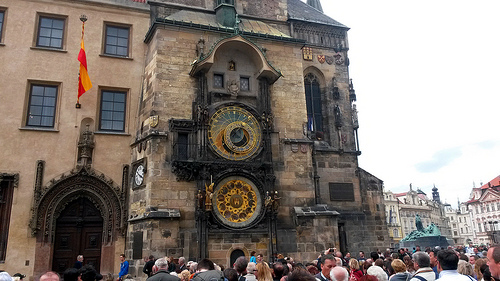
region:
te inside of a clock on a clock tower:
[205, 103, 280, 231]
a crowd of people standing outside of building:
[0, 248, 496, 278]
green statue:
[395, 210, 441, 250]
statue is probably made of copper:
[402, 210, 447, 248]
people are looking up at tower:
[0, 252, 481, 273]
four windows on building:
[25, 11, 126, 137]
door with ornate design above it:
[30, 115, 122, 275]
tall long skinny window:
[300, 60, 337, 141]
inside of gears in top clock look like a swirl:
[210, 97, 267, 164]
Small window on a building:
[28, 6, 68, 60]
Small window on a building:
[88, 11, 134, 73]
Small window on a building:
[212, 70, 222, 91]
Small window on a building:
[237, 72, 252, 98]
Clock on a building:
[123, 154, 158, 189]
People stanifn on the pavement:
[12, 245, 100, 280]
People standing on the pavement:
[145, 247, 258, 280]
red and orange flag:
[62, 36, 107, 112]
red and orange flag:
[56, 32, 101, 107]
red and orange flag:
[53, 20, 103, 123]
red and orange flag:
[65, 31, 106, 133]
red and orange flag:
[67, 30, 102, 115]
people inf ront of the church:
[132, 237, 438, 277]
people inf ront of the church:
[115, 91, 415, 276]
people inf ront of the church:
[142, 158, 450, 278]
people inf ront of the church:
[143, 156, 465, 279]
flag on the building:
[79, 9, 99, 94]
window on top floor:
[97, 21, 134, 57]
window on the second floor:
[91, 79, 134, 143]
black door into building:
[43, 187, 104, 277]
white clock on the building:
[129, 159, 146, 182]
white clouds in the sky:
[379, 5, 499, 136]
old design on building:
[200, 169, 268, 239]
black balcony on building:
[180, 97, 281, 178]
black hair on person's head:
[439, 248, 457, 267]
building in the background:
[450, 172, 498, 230]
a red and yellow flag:
[71, 19, 94, 100]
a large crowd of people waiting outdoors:
[118, 238, 498, 277]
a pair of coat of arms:
[314, 50, 339, 67]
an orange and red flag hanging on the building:
[70, 10, 97, 112]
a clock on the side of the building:
[128, 155, 150, 192]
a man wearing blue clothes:
[115, 248, 136, 280]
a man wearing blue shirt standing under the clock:
[115, 250, 134, 280]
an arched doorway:
[22, 159, 128, 279]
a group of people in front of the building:
[113, 249, 449, 280]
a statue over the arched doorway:
[73, 118, 98, 175]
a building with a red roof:
[470, 171, 499, 237]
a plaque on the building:
[320, 176, 361, 208]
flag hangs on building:
[72, 14, 93, 111]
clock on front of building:
[207, 103, 262, 160]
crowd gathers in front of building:
[12, 242, 499, 279]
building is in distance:
[390, 182, 463, 243]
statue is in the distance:
[397, 215, 450, 247]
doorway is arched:
[25, 160, 127, 279]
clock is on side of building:
[129, 158, 150, 191]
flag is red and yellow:
[69, 14, 94, 109]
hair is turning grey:
[412, 249, 432, 271]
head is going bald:
[332, 265, 348, 279]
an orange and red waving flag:
[75, 25, 92, 100]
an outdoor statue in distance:
[401, 211, 446, 247]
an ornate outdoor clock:
[166, 35, 281, 261]